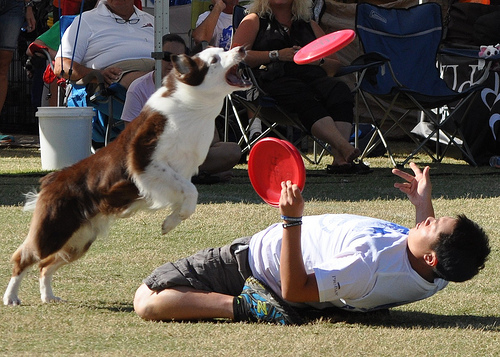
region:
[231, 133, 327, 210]
Two red frisbes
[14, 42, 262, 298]
Dog trying to catch a frisbee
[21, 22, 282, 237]
Brown and white dog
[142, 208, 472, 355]
Man in white shirt and gray shorts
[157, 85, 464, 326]
Man throwing a frisbee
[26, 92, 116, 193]
White bucket in grass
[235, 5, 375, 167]
Woman sitting in a lawn chair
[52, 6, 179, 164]
Man sitting in a lawn chair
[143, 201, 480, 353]
Man laying on grass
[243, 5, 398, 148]
Woman with a black shirt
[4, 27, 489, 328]
Man and dog playing with frisbees.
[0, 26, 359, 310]
Brown and white dog leaping for frisbee.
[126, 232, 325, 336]
Man laying back on legs.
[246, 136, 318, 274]
Man holding red frisbee.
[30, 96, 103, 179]
White bucket on edge of playing field.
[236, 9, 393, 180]
Woman sitting in lawn chair.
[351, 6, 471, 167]
Empty blue lawn chair.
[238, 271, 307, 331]
Man wearing black and blue tennis shoes.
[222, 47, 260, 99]
Gaping mouth on dog.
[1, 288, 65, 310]
Rear white paws on dog.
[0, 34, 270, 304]
brown and white dog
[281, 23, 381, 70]
red frisby in the air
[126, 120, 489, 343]
man holding red frisby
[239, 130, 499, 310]
man wearing white shirt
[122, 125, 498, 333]
man laying on grass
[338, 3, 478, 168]
blue folding chair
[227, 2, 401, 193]
lady sitting and watching the dog and man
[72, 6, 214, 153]
man sitting and watching man and dog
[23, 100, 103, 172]
white bucket next to man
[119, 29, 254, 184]
lady sitting on the grass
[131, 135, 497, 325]
Man on grass with two frisbees in his hand.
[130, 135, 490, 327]
Man holding two red frisbees.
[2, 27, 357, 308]
Dog attempting to catch a frisbee.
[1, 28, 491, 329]
Man and a dog showing off their frisbee skills.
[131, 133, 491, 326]
Man in shorts and a white t-shirt.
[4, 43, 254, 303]
Brown and white dog.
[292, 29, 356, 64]
Red frisbee in the air.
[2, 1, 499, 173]
Spectators sitting on chairs.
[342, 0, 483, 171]
Empty blue folding chair.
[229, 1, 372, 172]
Woman in black sitting in a lawn chair.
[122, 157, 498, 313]
The man is laying on the grass.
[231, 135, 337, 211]
The man has a Frisbee in his hand.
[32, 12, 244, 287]
The dog is brown and white.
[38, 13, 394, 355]
The dog is playing with the man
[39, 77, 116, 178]
A white bucket next to a man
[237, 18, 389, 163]
A person sitting in a lounge chair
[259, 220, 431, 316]
The man is wearing a white tshirt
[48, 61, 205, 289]
The dog is jumping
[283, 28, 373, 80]
The Frisbee is red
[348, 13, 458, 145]
The chair is blue.